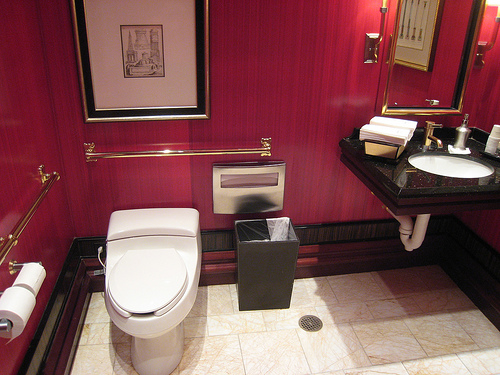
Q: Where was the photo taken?
A: In a bathroom.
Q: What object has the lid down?
A: The toilet.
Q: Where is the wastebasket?
A: Next to the toilet.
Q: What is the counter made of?
A: Marble.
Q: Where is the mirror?
A: Above the sink.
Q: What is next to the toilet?
A: The garbage can.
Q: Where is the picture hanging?
A: On the wall.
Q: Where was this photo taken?
A: In a bathroom.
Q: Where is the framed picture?
A: On the wall.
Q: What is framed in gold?
A: The picture.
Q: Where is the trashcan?
A: Next to the toilet.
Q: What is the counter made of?
A: Black marble.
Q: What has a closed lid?
A: The toilet.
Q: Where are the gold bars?
A: On the wall around the toilet.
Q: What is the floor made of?
A: Tiles.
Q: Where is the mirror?
A: Above the sink.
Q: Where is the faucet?
A: Above the sink.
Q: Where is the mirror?
A: Mounted on the wall.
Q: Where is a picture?
A: Hanging on wall over the toilet.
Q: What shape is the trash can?
A: Square.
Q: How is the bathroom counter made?
A: With black marble.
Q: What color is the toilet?
A: White.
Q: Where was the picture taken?
A: In a bathroom.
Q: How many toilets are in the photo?
A: One.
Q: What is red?
A: The walls.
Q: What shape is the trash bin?
A: Square.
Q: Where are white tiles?
A: On the floor.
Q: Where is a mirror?
A: On the wall.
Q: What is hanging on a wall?
A: Painting.